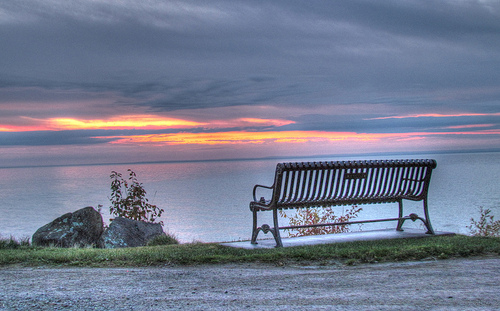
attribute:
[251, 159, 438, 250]
bench — metal, picturesque, steel, ornate, empty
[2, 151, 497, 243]
water — calm, large, blue, ocean water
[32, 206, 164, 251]
rocks — large, grey, speckled, blue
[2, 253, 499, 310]
path — dirt, gravel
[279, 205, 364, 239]
shrub — growing, small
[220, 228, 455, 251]
platform — cement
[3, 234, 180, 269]
grass — green, growing, short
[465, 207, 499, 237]
shrub — growing, small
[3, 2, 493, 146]
clouds — dark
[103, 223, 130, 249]
lichen — green, growing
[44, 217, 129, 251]
lichen — green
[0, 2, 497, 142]
sky — overcast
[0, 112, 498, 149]
sunset — orange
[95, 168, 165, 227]
leaves — small